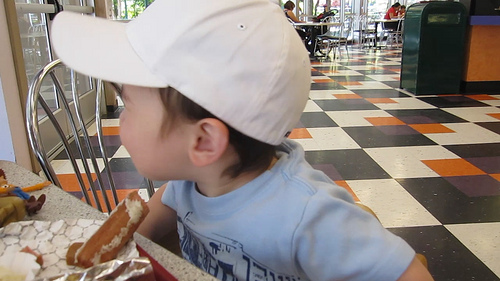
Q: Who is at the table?
A: A little boy.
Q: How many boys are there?
A: One.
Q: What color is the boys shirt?
A: Blue.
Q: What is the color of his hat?
A: White.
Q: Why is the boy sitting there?
A: He is eating.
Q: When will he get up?
A: When he's done eating.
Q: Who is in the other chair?
A: Noone.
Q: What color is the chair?
A: Grey.